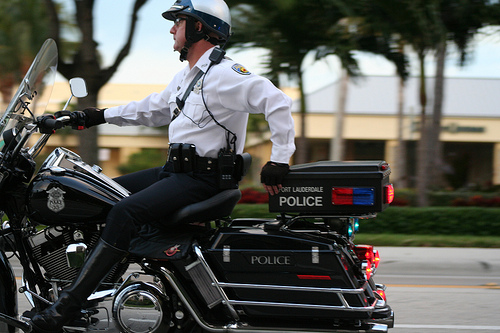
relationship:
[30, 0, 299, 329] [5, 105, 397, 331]
man on motorcycle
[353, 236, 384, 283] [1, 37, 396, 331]
taillight of motorcycle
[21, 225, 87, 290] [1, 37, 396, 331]
engine of motorcycle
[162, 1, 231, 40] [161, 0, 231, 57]
helmet on top of head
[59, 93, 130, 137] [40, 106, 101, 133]
hand on handle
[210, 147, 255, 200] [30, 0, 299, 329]
walky talky on man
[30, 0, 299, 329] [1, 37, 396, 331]
man riding motorcycle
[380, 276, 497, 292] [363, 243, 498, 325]
line painted on street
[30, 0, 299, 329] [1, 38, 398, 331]
man riding on motor cycle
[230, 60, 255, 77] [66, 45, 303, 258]
patch on uniform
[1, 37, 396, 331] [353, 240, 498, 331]
motorcycle on street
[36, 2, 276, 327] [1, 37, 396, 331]
man on motorcycle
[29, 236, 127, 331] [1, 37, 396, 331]
boot on motorcycle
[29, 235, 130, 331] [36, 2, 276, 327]
boot on man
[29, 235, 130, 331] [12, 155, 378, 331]
boot near motorcycle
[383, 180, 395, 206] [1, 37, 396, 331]
tail light on motorcycle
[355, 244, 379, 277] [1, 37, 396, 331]
light on motorcycle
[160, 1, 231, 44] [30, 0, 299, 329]
helmet on man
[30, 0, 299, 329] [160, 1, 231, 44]
man wears helmet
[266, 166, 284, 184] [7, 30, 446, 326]
glove on motorcycle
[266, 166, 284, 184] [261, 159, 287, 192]
glove worn on hand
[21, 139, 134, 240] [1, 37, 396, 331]
gas tank of a motorcycle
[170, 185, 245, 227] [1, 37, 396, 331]
seat of a motorcycle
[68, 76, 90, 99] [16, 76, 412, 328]
mirror of a motorcycle